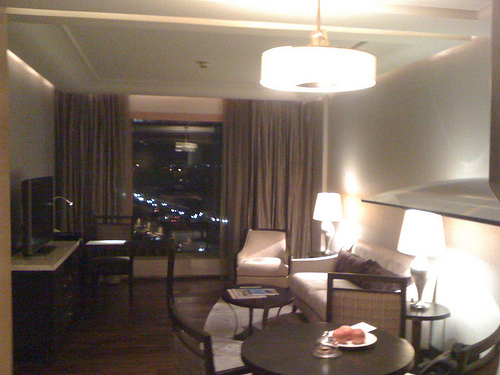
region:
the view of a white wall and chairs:
[279, 285, 304, 320]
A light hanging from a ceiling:
[260, 9, 378, 91]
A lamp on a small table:
[311, 192, 345, 251]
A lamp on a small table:
[399, 205, 444, 306]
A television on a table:
[20, 173, 65, 253]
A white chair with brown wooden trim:
[235, 226, 291, 285]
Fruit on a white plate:
[329, 323, 374, 348]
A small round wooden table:
[245, 322, 413, 371]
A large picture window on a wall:
[125, 115, 227, 255]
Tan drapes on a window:
[224, 101, 324, 253]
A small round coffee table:
[220, 283, 294, 332]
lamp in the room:
[286, 178, 362, 258]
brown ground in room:
[78, 310, 157, 360]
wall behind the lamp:
[343, 123, 427, 180]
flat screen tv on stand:
[13, 160, 83, 271]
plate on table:
[296, 310, 397, 372]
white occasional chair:
[228, 220, 328, 304]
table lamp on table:
[301, 169, 366, 279]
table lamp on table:
[361, 203, 470, 368]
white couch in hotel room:
[281, 231, 446, 332]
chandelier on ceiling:
[257, 0, 402, 100]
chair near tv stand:
[71, 214, 144, 295]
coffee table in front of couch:
[218, 267, 301, 352]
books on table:
[218, 275, 295, 332]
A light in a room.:
[386, 202, 453, 257]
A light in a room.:
[313, 189, 340, 223]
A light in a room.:
[251, 41, 386, 98]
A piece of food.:
[351, 328, 366, 345]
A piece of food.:
[333, 332, 346, 342]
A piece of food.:
[341, 325, 352, 341]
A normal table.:
[220, 278, 296, 325]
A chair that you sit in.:
[231, 225, 297, 294]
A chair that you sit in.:
[323, 272, 413, 342]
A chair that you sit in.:
[86, 214, 137, 312]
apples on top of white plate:
[323, 319, 378, 348]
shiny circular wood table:
[242, 317, 414, 374]